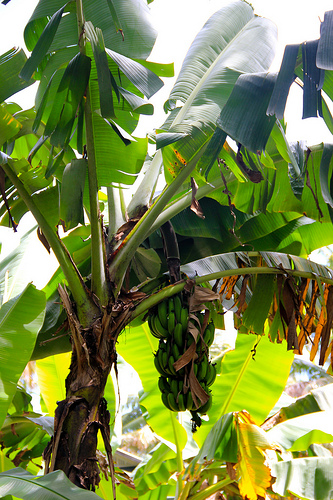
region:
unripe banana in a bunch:
[172, 318, 185, 348]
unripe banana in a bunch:
[177, 392, 186, 416]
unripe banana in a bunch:
[166, 391, 177, 415]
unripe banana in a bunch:
[168, 353, 177, 378]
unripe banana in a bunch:
[200, 327, 214, 352]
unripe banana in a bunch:
[198, 357, 208, 381]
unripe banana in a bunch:
[179, 304, 192, 326]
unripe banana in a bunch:
[153, 312, 169, 340]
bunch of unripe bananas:
[140, 266, 228, 429]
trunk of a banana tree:
[29, 269, 143, 499]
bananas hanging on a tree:
[147, 288, 224, 426]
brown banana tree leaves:
[219, 246, 332, 359]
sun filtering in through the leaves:
[226, 352, 332, 478]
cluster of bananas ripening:
[139, 284, 225, 428]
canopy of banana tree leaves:
[24, 29, 288, 184]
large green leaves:
[165, 49, 311, 180]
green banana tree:
[23, 144, 181, 384]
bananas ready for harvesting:
[154, 288, 233, 419]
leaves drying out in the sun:
[243, 242, 330, 358]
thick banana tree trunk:
[56, 303, 131, 488]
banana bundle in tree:
[146, 291, 217, 436]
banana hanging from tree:
[167, 393, 175, 412]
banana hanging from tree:
[175, 393, 187, 412]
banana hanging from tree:
[168, 357, 174, 375]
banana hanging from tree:
[206, 364, 214, 385]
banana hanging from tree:
[173, 320, 182, 344]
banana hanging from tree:
[165, 311, 176, 337]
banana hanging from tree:
[152, 319, 168, 338]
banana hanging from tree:
[159, 352, 166, 371]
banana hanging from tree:
[201, 392, 212, 414]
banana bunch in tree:
[153, 274, 210, 411]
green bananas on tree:
[146, 278, 215, 411]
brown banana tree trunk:
[52, 297, 141, 485]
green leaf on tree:
[28, 2, 152, 309]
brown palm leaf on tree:
[180, 279, 212, 414]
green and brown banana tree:
[0, 1, 332, 499]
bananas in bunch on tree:
[147, 276, 210, 418]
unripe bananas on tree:
[157, 278, 212, 415]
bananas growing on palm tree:
[147, 276, 211, 413]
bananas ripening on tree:
[151, 282, 210, 419]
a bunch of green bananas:
[146, 292, 215, 429]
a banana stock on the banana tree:
[156, 216, 176, 279]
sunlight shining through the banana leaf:
[213, 321, 299, 441]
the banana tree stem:
[44, 323, 123, 478]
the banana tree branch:
[80, 98, 104, 301]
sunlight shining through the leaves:
[109, 358, 141, 451]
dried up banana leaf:
[224, 409, 278, 496]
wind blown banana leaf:
[22, 0, 171, 200]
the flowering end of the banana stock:
[189, 409, 200, 429]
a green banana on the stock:
[165, 307, 175, 335]